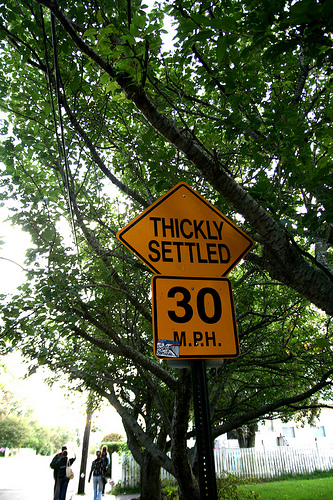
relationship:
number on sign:
[167, 286, 220, 322] [148, 274, 241, 363]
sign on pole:
[148, 274, 241, 363] [189, 357, 219, 498]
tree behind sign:
[0, 212, 331, 497] [148, 274, 241, 363]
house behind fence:
[213, 389, 331, 441] [110, 449, 331, 492]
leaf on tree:
[26, 268, 37, 280] [0, 212, 331, 497]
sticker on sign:
[154, 341, 180, 359] [148, 274, 241, 363]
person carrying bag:
[48, 447, 75, 499] [66, 459, 76, 482]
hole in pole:
[199, 455, 206, 459] [189, 357, 219, 498]